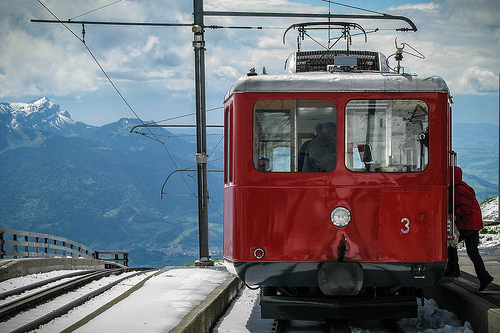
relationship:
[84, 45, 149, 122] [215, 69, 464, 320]
line in train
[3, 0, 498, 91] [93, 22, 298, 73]
clouds in sky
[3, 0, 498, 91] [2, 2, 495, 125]
clouds in sky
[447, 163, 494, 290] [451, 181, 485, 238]
child wearing shirt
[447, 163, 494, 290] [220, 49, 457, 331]
child boarding red train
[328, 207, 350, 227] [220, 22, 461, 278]
light on front of red train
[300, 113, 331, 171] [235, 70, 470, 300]
passenger waiting to sit on train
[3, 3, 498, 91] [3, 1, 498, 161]
clouds in sky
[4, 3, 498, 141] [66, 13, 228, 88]
sky has clouds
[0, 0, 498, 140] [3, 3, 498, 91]
sky has clouds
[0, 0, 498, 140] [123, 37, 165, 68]
sky has clouds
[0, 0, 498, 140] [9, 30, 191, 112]
sky has clouds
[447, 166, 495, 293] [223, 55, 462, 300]
child boarding train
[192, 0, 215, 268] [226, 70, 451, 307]
power line powering train